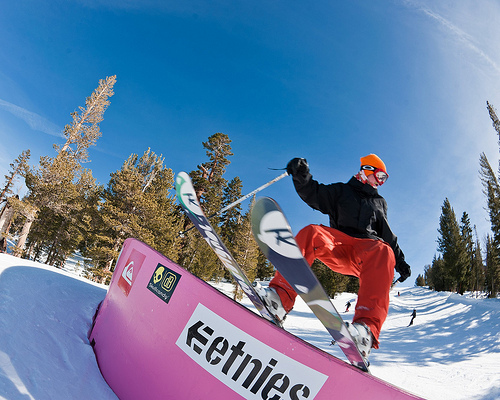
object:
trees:
[235, 190, 260, 301]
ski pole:
[173, 153, 312, 243]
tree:
[181, 132, 227, 283]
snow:
[374, 283, 500, 400]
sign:
[260, 214, 299, 256]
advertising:
[173, 302, 329, 400]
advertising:
[146, 262, 181, 304]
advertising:
[117, 248, 147, 296]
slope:
[1, 248, 497, 400]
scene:
[0, 0, 500, 400]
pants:
[266, 216, 396, 349]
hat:
[358, 153, 389, 176]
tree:
[0, 144, 32, 214]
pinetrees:
[413, 99, 499, 296]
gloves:
[268, 158, 313, 184]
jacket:
[281, 153, 411, 277]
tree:
[25, 71, 120, 269]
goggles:
[361, 164, 390, 185]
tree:
[101, 146, 182, 288]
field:
[2, 244, 494, 399]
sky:
[2, 8, 500, 284]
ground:
[248, 274, 498, 398]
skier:
[249, 151, 411, 368]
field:
[1, 62, 273, 238]